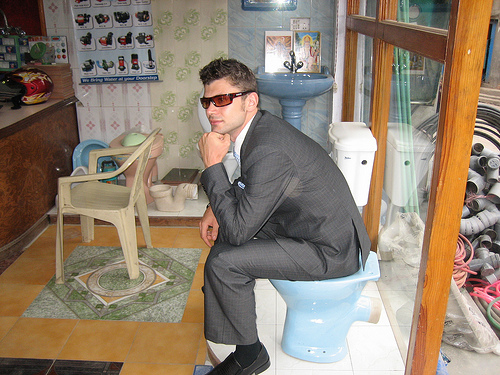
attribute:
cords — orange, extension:
[457, 235, 477, 250]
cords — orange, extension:
[455, 262, 477, 280]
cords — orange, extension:
[471, 285, 494, 299]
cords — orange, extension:
[490, 278, 497, 293]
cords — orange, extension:
[464, 276, 486, 286]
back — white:
[313, 120, 378, 212]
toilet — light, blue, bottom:
[259, 257, 381, 368]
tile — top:
[349, 325, 386, 373]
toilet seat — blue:
[279, 263, 379, 302]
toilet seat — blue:
[108, 132, 173, 163]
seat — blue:
[280, 245, 395, 373]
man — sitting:
[193, 56, 375, 373]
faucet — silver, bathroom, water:
[281, 49, 305, 73]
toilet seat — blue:
[261, 272, 388, 356]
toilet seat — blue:
[266, 248, 381, 364]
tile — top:
[205, 280, 405, 372]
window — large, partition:
[329, 0, 492, 363]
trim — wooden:
[418, 142, 476, 307]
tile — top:
[0, 217, 402, 374]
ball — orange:
[413, 234, 483, 304]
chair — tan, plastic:
[55, 127, 159, 286]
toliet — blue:
[266, 250, 381, 365]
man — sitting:
[146, 55, 362, 352]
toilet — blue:
[236, 98, 373, 370]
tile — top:
[353, 331, 405, 373]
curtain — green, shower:
[391, 5, 417, 219]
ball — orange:
[113, 120, 155, 158]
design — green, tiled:
[21, 245, 203, 322]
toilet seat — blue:
[259, 249, 390, 363]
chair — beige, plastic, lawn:
[86, 97, 177, 295]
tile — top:
[346, 322, 404, 371]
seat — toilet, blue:
[258, 249, 385, 372]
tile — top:
[275, 320, 355, 372]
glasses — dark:
[198, 89, 257, 109]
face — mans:
[198, 73, 264, 135]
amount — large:
[418, 141, 498, 295]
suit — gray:
[195, 106, 376, 349]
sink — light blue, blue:
[251, 64, 338, 134]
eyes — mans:
[200, 92, 230, 106]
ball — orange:
[117, 121, 146, 150]